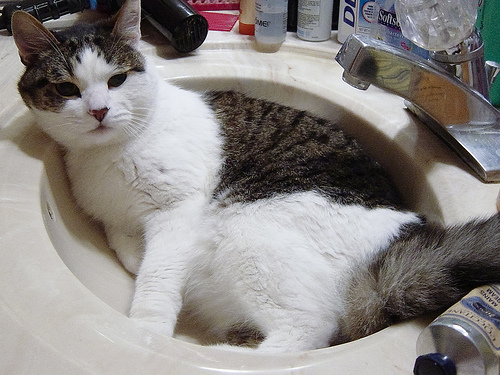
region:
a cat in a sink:
[3, 6, 477, 365]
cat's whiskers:
[110, 102, 187, 154]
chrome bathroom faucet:
[337, 21, 495, 160]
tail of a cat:
[342, 208, 497, 308]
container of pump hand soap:
[376, 1, 415, 58]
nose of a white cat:
[80, 102, 119, 126]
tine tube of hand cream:
[402, 276, 498, 373]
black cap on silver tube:
[406, 348, 458, 373]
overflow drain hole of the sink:
[37, 193, 67, 230]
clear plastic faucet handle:
[390, 1, 486, 53]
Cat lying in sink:
[9, 1, 499, 357]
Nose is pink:
[87, 89, 108, 121]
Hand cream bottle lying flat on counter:
[410, 278, 498, 373]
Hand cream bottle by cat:
[409, 285, 498, 374]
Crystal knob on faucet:
[395, 0, 479, 52]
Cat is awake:
[9, 0, 499, 364]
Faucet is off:
[319, 0, 499, 182]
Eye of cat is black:
[104, 66, 132, 91]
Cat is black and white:
[10, 0, 498, 357]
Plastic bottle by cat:
[253, 0, 288, 46]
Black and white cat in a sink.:
[8, 11, 491, 366]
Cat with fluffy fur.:
[100, 96, 425, 331]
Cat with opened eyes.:
[42, 65, 132, 101]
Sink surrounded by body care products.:
[5, 0, 445, 45]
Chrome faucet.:
[335, 30, 495, 180]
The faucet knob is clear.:
[391, 1, 481, 46]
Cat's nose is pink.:
[85, 105, 111, 120]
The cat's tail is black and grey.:
[416, 206, 496, 281]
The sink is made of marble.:
[157, 35, 389, 125]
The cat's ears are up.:
[10, 3, 145, 66]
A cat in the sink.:
[8, 1, 498, 353]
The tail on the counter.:
[380, 208, 499, 310]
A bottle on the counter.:
[411, 278, 497, 373]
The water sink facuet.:
[325, 36, 499, 179]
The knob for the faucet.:
[393, 1, 494, 65]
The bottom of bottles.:
[236, 1, 337, 46]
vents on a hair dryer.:
[163, 12, 218, 59]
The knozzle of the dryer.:
[139, 0, 218, 54]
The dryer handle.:
[6, 0, 66, 44]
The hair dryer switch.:
[90, 0, 104, 9]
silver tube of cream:
[414, 293, 498, 370]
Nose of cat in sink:
[86, 101, 112, 125]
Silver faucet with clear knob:
[331, 3, 498, 169]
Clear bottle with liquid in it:
[252, 1, 290, 47]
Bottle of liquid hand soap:
[368, 2, 430, 74]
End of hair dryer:
[141, 2, 212, 58]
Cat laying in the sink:
[7, 7, 411, 333]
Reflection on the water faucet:
[373, 47, 465, 114]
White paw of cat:
[131, 206, 206, 359]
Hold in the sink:
[41, 194, 62, 226]